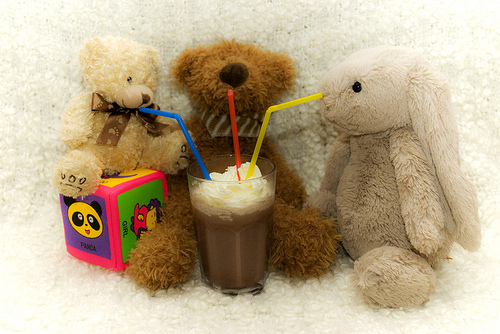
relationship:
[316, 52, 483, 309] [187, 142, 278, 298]
bunster attempts to drink chocolate soda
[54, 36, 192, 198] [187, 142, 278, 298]
baby bear attempts to drink chocolate soda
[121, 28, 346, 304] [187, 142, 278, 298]
bear attempts to drink chocolate soda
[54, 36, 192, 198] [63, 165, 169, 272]
baby bear sits on block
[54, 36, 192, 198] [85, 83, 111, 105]
baby bear has neck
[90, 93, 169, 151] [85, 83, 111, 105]
ribbon around neck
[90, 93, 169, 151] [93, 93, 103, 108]
ribbon has paw print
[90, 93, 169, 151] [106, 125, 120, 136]
ribbon has paw print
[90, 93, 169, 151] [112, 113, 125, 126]
ribbon has paw print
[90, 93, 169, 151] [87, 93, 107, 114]
ribbon has paw print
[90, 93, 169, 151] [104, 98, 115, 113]
ribbon has paw print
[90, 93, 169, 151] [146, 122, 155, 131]
ribbon has paw print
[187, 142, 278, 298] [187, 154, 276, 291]
chocolate soda in glass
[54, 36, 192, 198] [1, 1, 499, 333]
baby bear in front of blanket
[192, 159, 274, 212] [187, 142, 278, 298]
whipped cream on chocolate soda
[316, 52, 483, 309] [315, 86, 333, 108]
bunster has nose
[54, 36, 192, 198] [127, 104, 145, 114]
baby bear has chin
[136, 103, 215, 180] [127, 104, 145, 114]
straw rests beneath chin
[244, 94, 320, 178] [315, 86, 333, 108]
straw up nose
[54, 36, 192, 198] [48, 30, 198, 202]
baby bear has poodle fur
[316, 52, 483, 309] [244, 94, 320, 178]
bunster has straw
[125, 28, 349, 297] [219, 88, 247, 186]
bigger bear has red straw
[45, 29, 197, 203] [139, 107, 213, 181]
baby bear has straw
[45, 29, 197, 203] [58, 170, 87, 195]
baby bear has foot pad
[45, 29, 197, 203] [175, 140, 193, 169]
baby bear has foot pad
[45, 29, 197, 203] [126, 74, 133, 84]
baby bear has eye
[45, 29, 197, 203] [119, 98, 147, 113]
baby bear has mouth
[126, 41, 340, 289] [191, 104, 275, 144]
bear has neckerchief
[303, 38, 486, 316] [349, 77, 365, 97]
bunster has eye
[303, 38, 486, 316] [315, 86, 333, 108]
bunster has nose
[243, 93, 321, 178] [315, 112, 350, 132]
straw needs to be moved down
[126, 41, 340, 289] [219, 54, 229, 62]
bear has eye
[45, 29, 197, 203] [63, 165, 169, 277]
baby bear sits on block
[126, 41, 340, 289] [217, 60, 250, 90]
bear has nose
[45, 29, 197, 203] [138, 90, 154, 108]
baby bear has nose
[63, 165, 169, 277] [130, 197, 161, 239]
block has picture of girl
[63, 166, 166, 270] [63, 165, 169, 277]
outline on block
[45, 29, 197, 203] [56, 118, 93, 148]
baby bear has forepaw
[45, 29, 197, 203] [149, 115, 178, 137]
baby bear has [hidden] forepaw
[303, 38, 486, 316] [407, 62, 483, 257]
bunster has ear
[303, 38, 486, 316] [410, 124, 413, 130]
bunster has hidden 2nd ear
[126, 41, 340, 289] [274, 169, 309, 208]
bear has forepaw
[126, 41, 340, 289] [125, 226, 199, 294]
bear has hind paw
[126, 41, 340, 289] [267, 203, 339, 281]
bear has hind paw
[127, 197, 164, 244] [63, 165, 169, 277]
picture of girl on block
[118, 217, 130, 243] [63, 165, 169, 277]
'girl' [the word] on block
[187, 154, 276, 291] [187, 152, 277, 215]
glass has room behind cream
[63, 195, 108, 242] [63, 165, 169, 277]
'panda' on block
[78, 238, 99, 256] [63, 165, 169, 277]
'panda' [the word] on block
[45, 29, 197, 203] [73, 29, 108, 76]
baby bear has ear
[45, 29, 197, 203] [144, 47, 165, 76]
baby bear has ear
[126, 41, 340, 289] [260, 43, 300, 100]
bear has ear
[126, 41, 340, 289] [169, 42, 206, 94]
bear has ear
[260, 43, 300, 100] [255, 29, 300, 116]
ear  side of head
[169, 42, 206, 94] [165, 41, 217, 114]
ear  side of head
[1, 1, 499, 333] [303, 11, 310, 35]
blanket has little bare spot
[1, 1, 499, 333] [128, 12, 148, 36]
blanket has little bare spot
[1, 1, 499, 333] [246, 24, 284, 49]
blanket has little bare spot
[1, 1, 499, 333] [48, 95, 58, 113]
blanket has little bare spot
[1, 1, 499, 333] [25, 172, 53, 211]
blanket has little bare spot